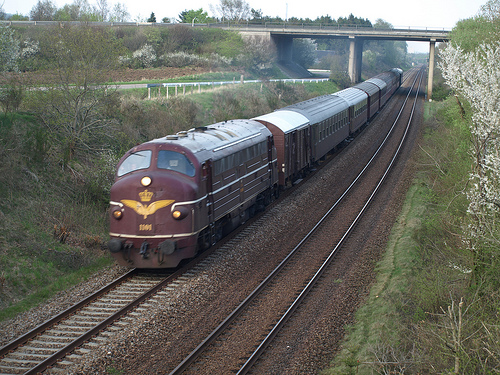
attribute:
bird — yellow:
[119, 196, 173, 218]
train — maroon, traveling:
[103, 65, 406, 270]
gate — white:
[90, 76, 327, 93]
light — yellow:
[169, 205, 183, 216]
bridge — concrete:
[237, 20, 463, 101]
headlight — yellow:
[114, 207, 121, 218]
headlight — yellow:
[171, 204, 184, 217]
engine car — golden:
[100, 117, 285, 279]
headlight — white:
[141, 176, 148, 184]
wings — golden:
[119, 200, 173, 216]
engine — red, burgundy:
[106, 119, 276, 269]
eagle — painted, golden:
[121, 192, 168, 222]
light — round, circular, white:
[138, 174, 153, 184]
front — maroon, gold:
[109, 145, 201, 273]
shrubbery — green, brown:
[373, 119, 485, 355]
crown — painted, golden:
[136, 190, 154, 202]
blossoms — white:
[439, 41, 485, 150]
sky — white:
[0, 0, 499, 30]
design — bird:
[119, 196, 179, 220]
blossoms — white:
[436, 36, 499, 218]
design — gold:
[119, 198, 174, 218]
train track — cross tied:
[167, 71, 424, 373]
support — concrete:
[346, 33, 362, 83]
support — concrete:
[425, 36, 438, 100]